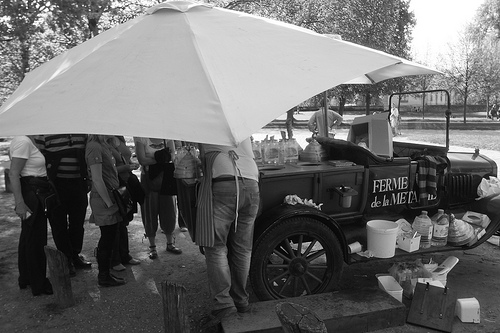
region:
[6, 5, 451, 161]
large cantilever umbrella suspended in air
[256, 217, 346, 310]
front wheel of a car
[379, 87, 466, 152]
windshield of a car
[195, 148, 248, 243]
person wearing an apron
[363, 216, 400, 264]
white plastic bucket off ground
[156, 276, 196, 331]
wooden post in ground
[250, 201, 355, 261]
front fender of vehicle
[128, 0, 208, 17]
top of an umbrella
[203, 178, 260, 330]
jeans being worn by vendor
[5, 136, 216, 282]
people waiting in line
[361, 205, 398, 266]
bucket on a truck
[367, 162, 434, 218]
name of a truck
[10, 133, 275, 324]
people under a tent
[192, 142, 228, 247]
apron on a man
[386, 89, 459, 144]
window of an antique car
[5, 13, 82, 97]
leaves on a tree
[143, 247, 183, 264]
shoes on a woman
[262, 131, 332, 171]
jugs in a trunk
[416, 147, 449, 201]
blanket on car door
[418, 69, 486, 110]
buildings across the street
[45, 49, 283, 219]
People under large umbrella.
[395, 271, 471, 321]
Bag sitting on ground.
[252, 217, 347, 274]
Black tire on vehicle.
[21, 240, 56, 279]
Person wearing black pants.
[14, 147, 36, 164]
Person wearing white shirt.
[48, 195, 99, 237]
Person wearing dark pants.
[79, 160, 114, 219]
Person wearing gray dress.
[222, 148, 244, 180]
Person wearing white shirt.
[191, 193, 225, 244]
Person wearing apron over clothes.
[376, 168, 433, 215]
White writing on side of vehicle.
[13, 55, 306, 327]
People under a umbrella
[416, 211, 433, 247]
Bottle on the car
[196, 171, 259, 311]
person wearing blue jeans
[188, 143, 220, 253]
person wearing a apron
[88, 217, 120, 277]
person wearing black pants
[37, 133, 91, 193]
person wearing striped shirt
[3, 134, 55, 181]
woman wearing a white shirt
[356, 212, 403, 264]
bucket on a car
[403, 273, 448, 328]
sachet on the ground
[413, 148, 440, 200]
shirt on the car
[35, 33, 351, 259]
people standing under umbrella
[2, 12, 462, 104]
group of trees behind people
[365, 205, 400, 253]
white bucket on car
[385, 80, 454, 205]
dark frame on windscreen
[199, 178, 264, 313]
person has dark jeans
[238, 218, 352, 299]
dark wheel on car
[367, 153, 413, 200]
white name on car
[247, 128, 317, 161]
small bottles on car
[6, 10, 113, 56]
thin leaves on tree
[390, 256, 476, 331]
small basket under car